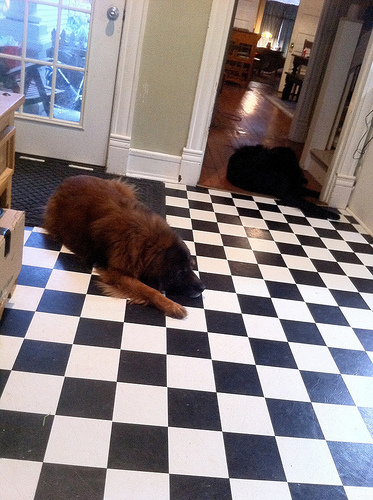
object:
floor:
[0, 152, 373, 500]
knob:
[107, 6, 120, 21]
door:
[0, 0, 128, 166]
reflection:
[240, 80, 263, 120]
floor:
[196, 75, 328, 204]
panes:
[53, 67, 85, 129]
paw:
[172, 304, 188, 321]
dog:
[43, 174, 207, 319]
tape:
[0, 227, 12, 258]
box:
[0, 206, 25, 319]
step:
[310, 145, 333, 168]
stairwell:
[310, 28, 373, 173]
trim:
[319, 32, 373, 210]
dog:
[226, 144, 341, 220]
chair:
[224, 51, 254, 86]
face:
[164, 257, 206, 298]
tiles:
[281, 254, 318, 273]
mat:
[10, 152, 165, 231]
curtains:
[256, 0, 299, 59]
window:
[256, 0, 301, 57]